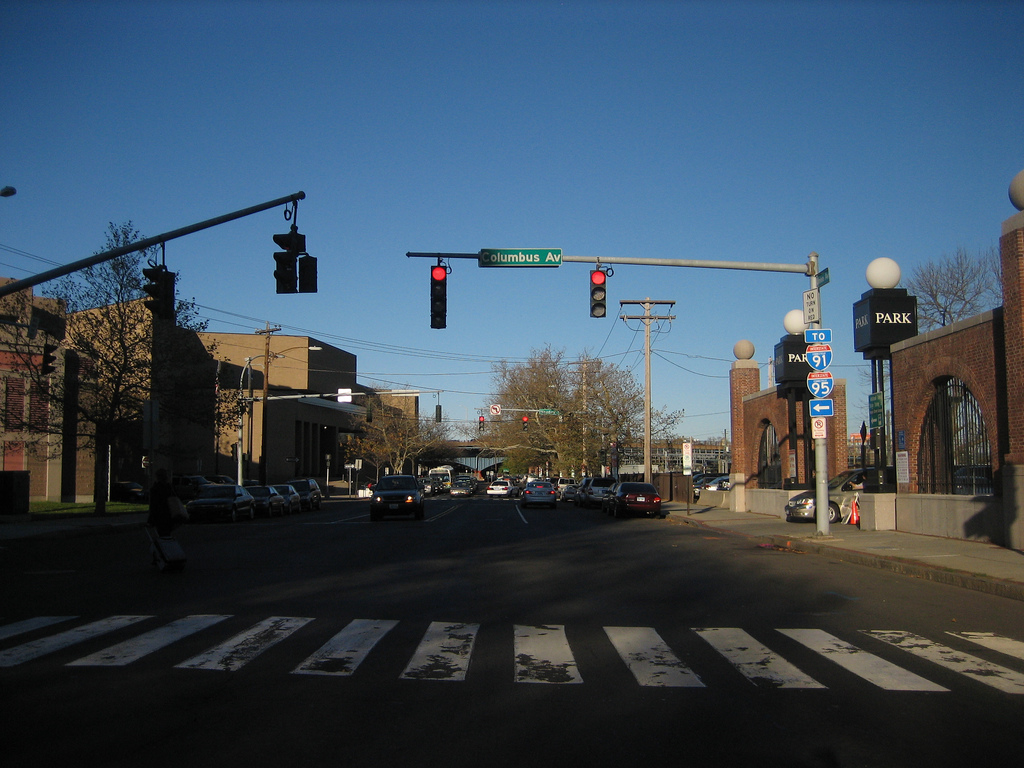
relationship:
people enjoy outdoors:
[219, 463, 386, 500] [21, 231, 1022, 761]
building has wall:
[356, 376, 432, 482] [399, 400, 413, 440]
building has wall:
[204, 320, 371, 483] [269, 348, 311, 388]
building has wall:
[381, 382, 427, 478] [390, 413, 412, 444]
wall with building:
[338, 370, 540, 492] [224, 331, 534, 565]